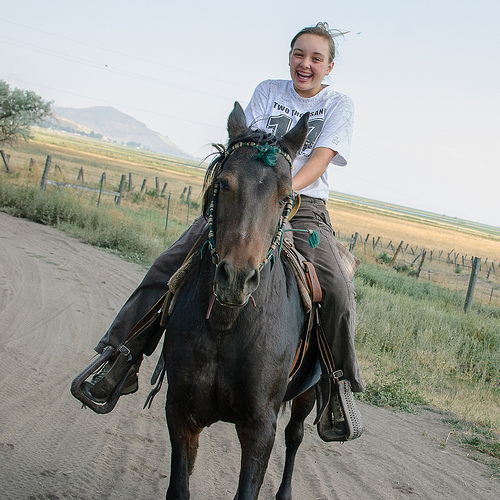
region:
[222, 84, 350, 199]
A white t-shirt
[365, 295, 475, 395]
Grass in the photo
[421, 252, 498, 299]
Fence in the photo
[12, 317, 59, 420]
dirt road in the photo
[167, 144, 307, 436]
A horse in the photo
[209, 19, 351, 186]
A woman smiling in the photo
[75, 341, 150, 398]
A brown shoe in the photo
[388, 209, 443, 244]
A field with grass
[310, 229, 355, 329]
Gray pants in the photo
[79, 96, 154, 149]
A hill in the background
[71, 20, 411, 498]
girl riding a horse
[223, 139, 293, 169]
decorative piece on horse's rein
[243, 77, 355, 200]
gray shirt on girl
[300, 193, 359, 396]
pant leg of girl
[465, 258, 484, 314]
wooden post in field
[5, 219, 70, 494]
sand on the ground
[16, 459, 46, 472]
track in the sand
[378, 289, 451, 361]
field of wild grass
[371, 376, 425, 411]
patch of shorter grass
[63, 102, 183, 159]
mountain in the background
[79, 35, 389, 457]
the girl is in on the horse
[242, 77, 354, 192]
the shirt is white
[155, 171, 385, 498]
the horse is black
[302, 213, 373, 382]
the pants are dark grey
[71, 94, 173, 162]
hill is in the background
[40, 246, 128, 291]
tracks are on the sand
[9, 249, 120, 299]
the ground is is brown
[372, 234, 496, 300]
the fence is wooden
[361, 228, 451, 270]
the fence is barbed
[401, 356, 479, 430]
the grass is brown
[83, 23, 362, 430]
A young girl on a horse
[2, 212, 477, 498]
A dirt trail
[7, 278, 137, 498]
some tire tracks on the dirt road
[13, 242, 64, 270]
some grass on the dirt road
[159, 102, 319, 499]
A brown horse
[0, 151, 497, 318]
A large fence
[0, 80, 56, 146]
the top of a tree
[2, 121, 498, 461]
A grassy landscape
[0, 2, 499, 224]
A clear blue sky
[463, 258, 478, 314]
A wooden post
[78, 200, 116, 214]
short green and brown grass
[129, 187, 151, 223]
short green and brown grass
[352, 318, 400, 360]
short green and brown grass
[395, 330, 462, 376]
short green and brown grass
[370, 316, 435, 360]
short green and brown grass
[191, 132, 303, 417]
black and brown horse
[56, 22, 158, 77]
white clouds in blue sky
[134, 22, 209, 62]
white clouds in blue sky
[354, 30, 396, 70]
white clouds in blue sky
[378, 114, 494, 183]
white clouds in blue sky